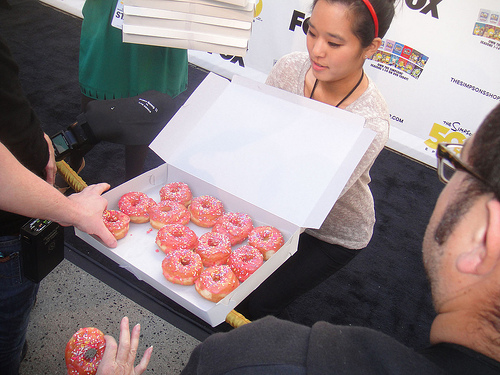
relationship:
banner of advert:
[249, 1, 500, 176] [290, 7, 434, 82]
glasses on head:
[434, 139, 491, 196] [406, 98, 499, 321]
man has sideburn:
[175, 103, 498, 371] [434, 181, 483, 244]